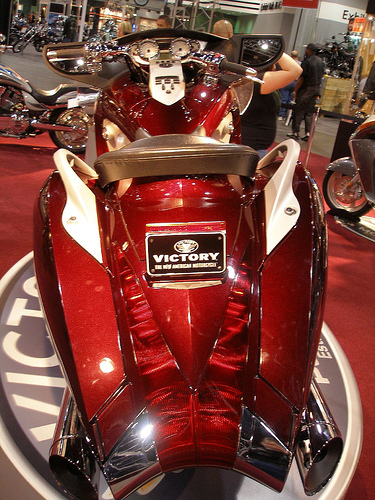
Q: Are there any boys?
A: No, there are no boys.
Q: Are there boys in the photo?
A: No, there are no boys.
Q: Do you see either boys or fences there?
A: No, there are no boys or fences.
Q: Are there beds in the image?
A: No, there are no beds.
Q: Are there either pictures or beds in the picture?
A: No, there are no beds or pictures.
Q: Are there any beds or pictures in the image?
A: No, there are no beds or pictures.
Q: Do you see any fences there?
A: No, there are no fences.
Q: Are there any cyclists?
A: No, there are no cyclists.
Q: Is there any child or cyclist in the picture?
A: No, there are no cyclists or children.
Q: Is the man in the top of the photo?
A: Yes, the man is in the top of the image.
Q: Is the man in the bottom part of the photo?
A: No, the man is in the top of the image.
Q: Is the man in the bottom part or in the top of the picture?
A: The man is in the top of the image.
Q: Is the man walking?
A: Yes, the man is walking.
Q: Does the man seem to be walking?
A: Yes, the man is walking.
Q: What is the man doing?
A: The man is walking.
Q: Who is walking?
A: The man is walking.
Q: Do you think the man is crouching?
A: No, the man is walking.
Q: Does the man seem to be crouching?
A: No, the man is walking.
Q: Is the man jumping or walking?
A: The man is walking.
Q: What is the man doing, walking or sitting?
A: The man is walking.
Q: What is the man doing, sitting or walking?
A: The man is walking.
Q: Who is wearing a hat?
A: The man is wearing a hat.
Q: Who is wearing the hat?
A: The man is wearing a hat.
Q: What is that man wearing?
A: The man is wearing a hat.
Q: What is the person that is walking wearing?
A: The man is wearing a hat.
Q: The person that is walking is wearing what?
A: The man is wearing a hat.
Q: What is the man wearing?
A: The man is wearing a hat.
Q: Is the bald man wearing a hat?
A: Yes, the man is wearing a hat.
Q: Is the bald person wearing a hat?
A: Yes, the man is wearing a hat.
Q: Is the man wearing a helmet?
A: No, the man is wearing a hat.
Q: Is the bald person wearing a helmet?
A: No, the man is wearing a hat.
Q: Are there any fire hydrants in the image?
A: No, there are no fire hydrants.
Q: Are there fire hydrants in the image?
A: No, there are no fire hydrants.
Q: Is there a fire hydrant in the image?
A: No, there are no fire hydrants.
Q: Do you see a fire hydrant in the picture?
A: No, there are no fire hydrants.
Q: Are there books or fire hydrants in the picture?
A: No, there are no fire hydrants or books.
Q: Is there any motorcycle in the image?
A: Yes, there is a motorcycle.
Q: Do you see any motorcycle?
A: Yes, there is a motorcycle.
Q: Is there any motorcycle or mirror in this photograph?
A: Yes, there is a motorcycle.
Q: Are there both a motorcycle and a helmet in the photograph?
A: No, there is a motorcycle but no helmets.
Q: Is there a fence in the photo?
A: No, there are no fences.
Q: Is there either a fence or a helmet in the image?
A: No, there are no fences or helmets.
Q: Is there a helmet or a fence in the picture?
A: No, there are no fences or helmets.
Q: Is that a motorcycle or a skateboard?
A: That is a motorcycle.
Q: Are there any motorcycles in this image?
A: Yes, there is a motorcycle.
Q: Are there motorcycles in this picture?
A: Yes, there is a motorcycle.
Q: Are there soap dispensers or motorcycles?
A: Yes, there is a motorcycle.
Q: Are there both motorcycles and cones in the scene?
A: No, there is a motorcycle but no cones.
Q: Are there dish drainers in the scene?
A: No, there are no dish drainers.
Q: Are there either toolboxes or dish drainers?
A: No, there are no dish drainers or toolboxes.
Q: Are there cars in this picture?
A: No, there are no cars.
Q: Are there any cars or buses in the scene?
A: No, there are no cars or buses.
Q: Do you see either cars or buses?
A: No, there are no cars or buses.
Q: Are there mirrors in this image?
A: Yes, there is a mirror.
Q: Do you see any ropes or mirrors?
A: Yes, there is a mirror.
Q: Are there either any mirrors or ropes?
A: Yes, there is a mirror.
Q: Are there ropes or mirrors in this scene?
A: Yes, there is a mirror.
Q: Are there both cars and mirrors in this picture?
A: No, there is a mirror but no cars.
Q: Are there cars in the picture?
A: No, there are no cars.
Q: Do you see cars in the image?
A: No, there are no cars.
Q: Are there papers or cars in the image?
A: No, there are no cars or papers.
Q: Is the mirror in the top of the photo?
A: Yes, the mirror is in the top of the image.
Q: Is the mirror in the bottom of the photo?
A: No, the mirror is in the top of the image.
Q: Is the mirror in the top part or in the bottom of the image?
A: The mirror is in the top of the image.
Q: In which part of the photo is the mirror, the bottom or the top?
A: The mirror is in the top of the image.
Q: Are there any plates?
A: Yes, there is a plate.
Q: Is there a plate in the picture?
A: Yes, there is a plate.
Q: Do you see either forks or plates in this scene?
A: Yes, there is a plate.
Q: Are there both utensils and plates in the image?
A: No, there is a plate but no utensils.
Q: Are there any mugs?
A: No, there are no mugs.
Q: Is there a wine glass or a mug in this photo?
A: No, there are no mugs or wine glasses.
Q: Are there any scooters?
A: Yes, there is a scooter.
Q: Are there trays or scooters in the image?
A: Yes, there is a scooter.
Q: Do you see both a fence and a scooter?
A: No, there is a scooter but no fences.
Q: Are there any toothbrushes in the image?
A: No, there are no toothbrushes.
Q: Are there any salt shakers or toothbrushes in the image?
A: No, there are no toothbrushes or salt shakers.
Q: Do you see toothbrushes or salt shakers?
A: No, there are no toothbrushes or salt shakers.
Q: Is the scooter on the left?
A: Yes, the scooter is on the left of the image.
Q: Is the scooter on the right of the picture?
A: No, the scooter is on the left of the image.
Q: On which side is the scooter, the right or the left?
A: The scooter is on the left of the image.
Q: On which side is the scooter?
A: The scooter is on the left of the image.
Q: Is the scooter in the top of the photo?
A: Yes, the scooter is in the top of the image.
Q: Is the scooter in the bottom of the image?
A: No, the scooter is in the top of the image.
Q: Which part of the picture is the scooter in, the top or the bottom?
A: The scooter is in the top of the image.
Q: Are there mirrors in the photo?
A: Yes, there is a mirror.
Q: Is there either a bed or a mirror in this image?
A: Yes, there is a mirror.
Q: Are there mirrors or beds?
A: Yes, there is a mirror.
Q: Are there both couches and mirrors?
A: No, there is a mirror but no couches.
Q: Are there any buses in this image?
A: No, there are no buses.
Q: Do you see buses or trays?
A: No, there are no buses or trays.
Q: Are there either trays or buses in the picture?
A: No, there are no buses or trays.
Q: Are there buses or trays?
A: No, there are no buses or trays.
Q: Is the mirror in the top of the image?
A: Yes, the mirror is in the top of the image.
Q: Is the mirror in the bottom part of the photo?
A: No, the mirror is in the top of the image.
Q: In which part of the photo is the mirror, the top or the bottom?
A: The mirror is in the top of the image.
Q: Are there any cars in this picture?
A: No, there are no cars.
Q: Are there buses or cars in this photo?
A: No, there are no cars or buses.